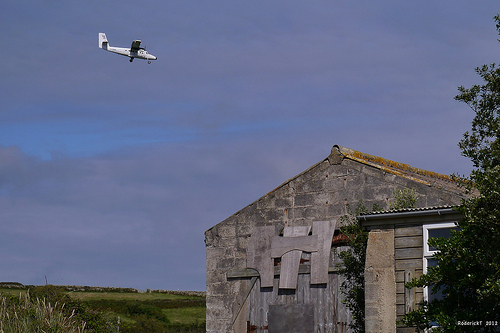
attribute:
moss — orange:
[322, 138, 475, 192]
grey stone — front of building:
[190, 133, 460, 323]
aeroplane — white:
[84, 20, 161, 73]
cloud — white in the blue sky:
[152, 137, 230, 205]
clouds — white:
[4, 7, 498, 288]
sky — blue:
[7, 0, 494, 290]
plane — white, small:
[93, 22, 156, 67]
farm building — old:
[204, 151, 491, 332]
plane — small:
[95, 29, 165, 65]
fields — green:
[2, 278, 202, 332]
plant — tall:
[6, 282, 116, 332]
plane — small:
[93, 31, 160, 65]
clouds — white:
[58, 68, 113, 128]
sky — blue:
[15, 124, 96, 155]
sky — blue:
[42, 148, 99, 223]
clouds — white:
[77, 143, 109, 191]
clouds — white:
[66, 160, 123, 217]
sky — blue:
[61, 110, 98, 168]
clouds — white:
[54, 149, 141, 246]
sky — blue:
[93, 91, 161, 153]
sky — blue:
[326, 43, 385, 96]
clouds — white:
[65, 150, 90, 206]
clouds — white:
[82, 169, 131, 217]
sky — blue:
[100, 175, 171, 215]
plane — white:
[70, 23, 179, 78]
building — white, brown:
[221, 162, 395, 292]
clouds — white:
[20, 67, 72, 107]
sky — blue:
[57, 156, 122, 213]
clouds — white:
[72, 177, 126, 235]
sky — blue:
[106, 100, 140, 140]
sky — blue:
[110, 213, 134, 236]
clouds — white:
[95, 121, 125, 152]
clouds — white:
[37, 174, 141, 236]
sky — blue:
[94, 83, 205, 193]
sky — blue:
[242, 46, 282, 75]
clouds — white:
[92, 121, 125, 190]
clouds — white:
[149, 146, 199, 183]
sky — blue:
[73, 173, 137, 223]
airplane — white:
[82, 20, 181, 80]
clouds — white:
[15, 43, 42, 82]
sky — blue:
[66, 111, 114, 162]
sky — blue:
[86, 156, 119, 199]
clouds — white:
[185, 120, 220, 155]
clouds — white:
[96, 193, 133, 230]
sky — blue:
[85, 136, 100, 170]